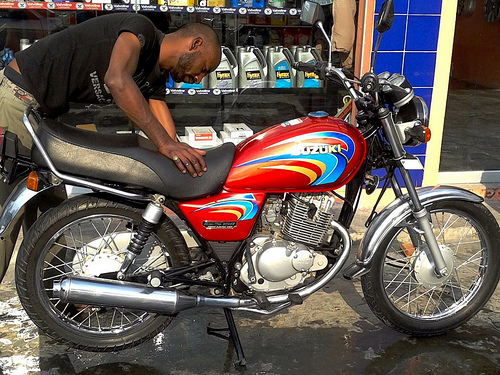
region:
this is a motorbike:
[267, 74, 397, 321]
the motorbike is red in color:
[252, 150, 333, 195]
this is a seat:
[206, 146, 227, 183]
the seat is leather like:
[67, 138, 139, 173]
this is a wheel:
[33, 202, 116, 345]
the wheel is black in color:
[69, 195, 89, 214]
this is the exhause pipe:
[49, 275, 142, 310]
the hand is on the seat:
[152, 135, 205, 177]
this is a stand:
[212, 311, 247, 368]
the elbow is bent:
[101, 62, 132, 94]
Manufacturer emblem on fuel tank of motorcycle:
[288, 145, 348, 154]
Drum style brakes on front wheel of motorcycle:
[410, 243, 460, 293]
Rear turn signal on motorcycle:
[25, 167, 52, 192]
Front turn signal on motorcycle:
[407, 121, 438, 143]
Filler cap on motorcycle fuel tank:
[303, 103, 330, 120]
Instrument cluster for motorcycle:
[370, 63, 415, 112]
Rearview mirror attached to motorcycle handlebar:
[371, 0, 394, 86]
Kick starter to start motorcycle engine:
[243, 233, 263, 288]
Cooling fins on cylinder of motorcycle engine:
[280, 191, 341, 247]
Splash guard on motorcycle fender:
[340, 253, 372, 281]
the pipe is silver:
[43, 272, 283, 363]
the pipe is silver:
[13, 265, 138, 327]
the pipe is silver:
[62, 272, 157, 324]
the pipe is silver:
[65, 240, 165, 346]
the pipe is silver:
[92, 254, 230, 371]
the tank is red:
[230, 114, 325, 209]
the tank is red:
[263, 115, 360, 220]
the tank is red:
[220, 137, 370, 277]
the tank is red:
[259, 42, 393, 260]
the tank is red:
[187, 62, 367, 226]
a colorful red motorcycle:
[17, 54, 499, 350]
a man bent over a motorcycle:
[3, 14, 495, 351]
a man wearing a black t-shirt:
[0, 11, 222, 175]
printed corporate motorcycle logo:
[286, 140, 343, 157]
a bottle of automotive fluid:
[265, 44, 293, 90]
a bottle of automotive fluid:
[235, 44, 266, 89]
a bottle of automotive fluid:
[292, 42, 322, 90]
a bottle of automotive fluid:
[206, 44, 240, 95]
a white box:
[180, 123, 214, 142]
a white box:
[220, 117, 250, 139]